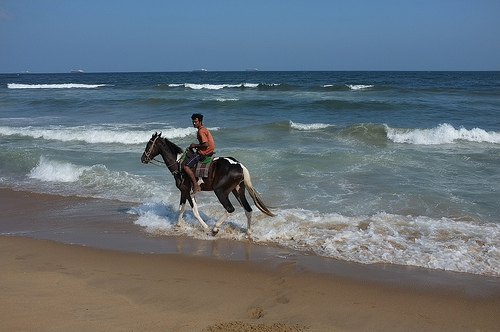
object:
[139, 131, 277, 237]
black horse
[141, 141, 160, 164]
face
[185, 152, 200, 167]
black shorts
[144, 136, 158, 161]
bridle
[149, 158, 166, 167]
reins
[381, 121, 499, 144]
waves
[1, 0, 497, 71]
sky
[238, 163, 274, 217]
tail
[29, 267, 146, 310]
sand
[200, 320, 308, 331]
footprints sand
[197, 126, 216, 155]
orange shirt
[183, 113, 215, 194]
boy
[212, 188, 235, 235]
legs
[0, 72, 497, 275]
water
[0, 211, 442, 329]
beach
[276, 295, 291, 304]
footprint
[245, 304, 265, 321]
footprint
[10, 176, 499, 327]
shore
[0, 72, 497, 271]
ocean